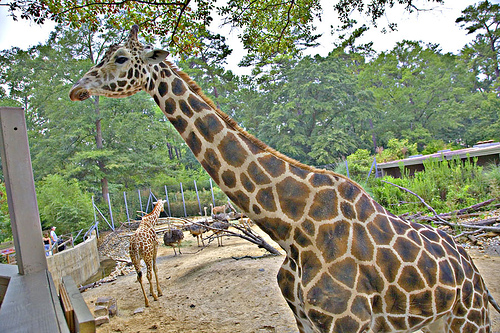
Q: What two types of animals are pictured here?
A: Giraffes and ostriches.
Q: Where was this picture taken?
A: At a zoo.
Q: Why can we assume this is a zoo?
A: Because the animals are gated in.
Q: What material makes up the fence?
A: Wood.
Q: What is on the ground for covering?
A: Sand.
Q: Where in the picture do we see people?
A: On the left.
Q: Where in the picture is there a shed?
A: To the right.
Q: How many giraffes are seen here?
A: Two.